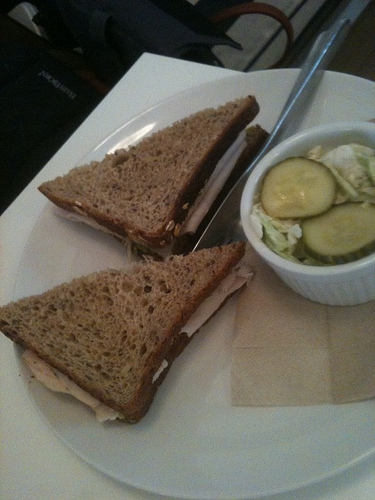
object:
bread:
[0, 238, 247, 424]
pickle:
[258, 156, 337, 220]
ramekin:
[239, 121, 374, 306]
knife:
[192, 0, 372, 252]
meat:
[195, 309, 209, 326]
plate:
[0, 50, 375, 499]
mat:
[0, 51, 373, 498]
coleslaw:
[248, 143, 375, 267]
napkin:
[228, 251, 374, 406]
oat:
[166, 221, 175, 232]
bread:
[37, 96, 261, 249]